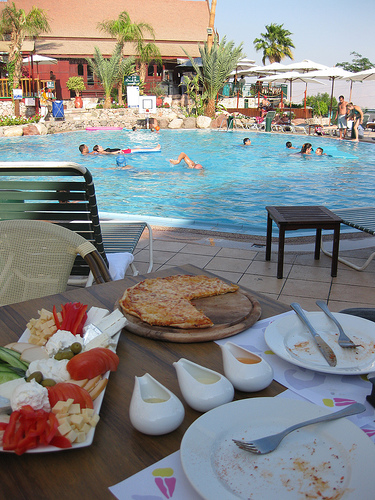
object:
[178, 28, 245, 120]
palm trees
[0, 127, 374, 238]
pool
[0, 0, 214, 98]
resort